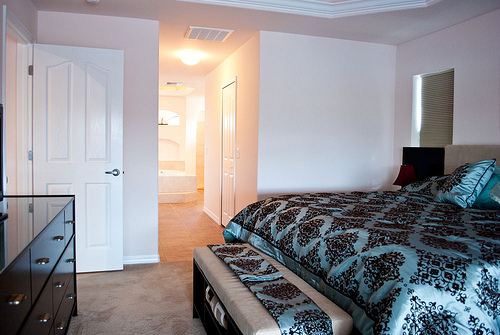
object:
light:
[171, 45, 213, 70]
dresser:
[0, 191, 86, 335]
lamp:
[388, 161, 421, 188]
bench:
[180, 238, 360, 335]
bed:
[222, 185, 500, 334]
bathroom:
[158, 87, 205, 203]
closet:
[210, 76, 245, 228]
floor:
[168, 209, 206, 238]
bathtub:
[158, 162, 199, 205]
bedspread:
[387, 252, 499, 335]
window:
[415, 65, 458, 148]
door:
[35, 44, 129, 280]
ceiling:
[161, 8, 240, 69]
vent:
[172, 19, 241, 48]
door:
[208, 75, 248, 230]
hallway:
[169, 82, 221, 209]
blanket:
[251, 186, 411, 218]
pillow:
[426, 156, 498, 209]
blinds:
[421, 118, 452, 126]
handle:
[99, 163, 123, 181]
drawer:
[46, 232, 81, 326]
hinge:
[21, 149, 44, 162]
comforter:
[433, 154, 499, 209]